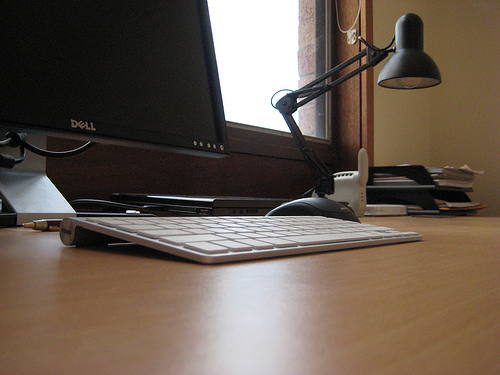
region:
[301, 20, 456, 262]
black desk lamp in photo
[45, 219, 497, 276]
white keyboard in photo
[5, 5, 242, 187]
black Dell computer monitor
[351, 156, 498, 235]
black paper rack in photo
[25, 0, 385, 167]
window behind computer desk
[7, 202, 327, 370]
wooden computer desk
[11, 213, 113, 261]
one pen visible in photo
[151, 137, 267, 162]
five buttons visible on monitor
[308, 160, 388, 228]
white modem in photo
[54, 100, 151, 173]
Dell written on monitor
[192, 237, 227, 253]
a white key on a keyboard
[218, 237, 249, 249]
a white key on a keyboard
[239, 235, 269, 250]
a white key on a keyboard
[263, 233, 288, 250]
a white key on a keyboard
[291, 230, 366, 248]
a white key on a keyboard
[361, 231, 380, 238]
a white key on a keyboard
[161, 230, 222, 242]
a white key on a keyboard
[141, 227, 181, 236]
a white key on a keyboard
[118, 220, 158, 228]
a white key on a keyboard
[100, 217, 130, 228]
a white key on a keyboard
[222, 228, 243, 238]
a white key on a keyboard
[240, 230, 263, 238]
a white key on a keyboard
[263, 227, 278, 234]
a white key on a keyboard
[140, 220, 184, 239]
a white key on a keyboard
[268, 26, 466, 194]
A black desk lamp.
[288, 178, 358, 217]
A black computer mouse.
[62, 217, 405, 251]
A white keyboard.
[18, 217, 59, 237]
A pen for writing.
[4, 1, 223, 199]
A black computer monitor.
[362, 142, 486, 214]
A filing system with stacks of paper.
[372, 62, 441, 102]
A light bulb in the desk lamp.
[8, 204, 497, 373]
A wooden desk to work at.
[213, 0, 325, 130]
A window in the room.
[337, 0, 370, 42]
A drawstring for window treatments.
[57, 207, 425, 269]
white keyboard on a desk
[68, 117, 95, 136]
word "dell" on a monitor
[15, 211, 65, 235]
part of an ink pen behind a keyboard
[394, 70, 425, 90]
light bulb in a lamp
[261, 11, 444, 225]
black desk lamp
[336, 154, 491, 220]
stack of papers in an organizer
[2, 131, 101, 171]
black wires under the monitor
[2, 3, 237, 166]
black monitor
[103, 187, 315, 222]
laptop closed on desk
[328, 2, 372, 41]
string for blinds